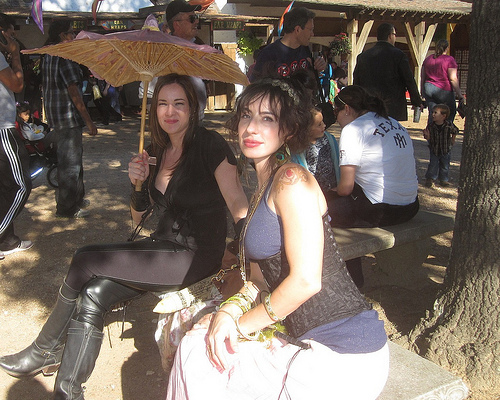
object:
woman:
[165, 80, 388, 400]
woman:
[1, 73, 248, 399]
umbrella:
[20, 13, 250, 192]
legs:
[1, 235, 192, 399]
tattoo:
[271, 164, 308, 195]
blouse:
[134, 124, 239, 254]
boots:
[0, 274, 145, 398]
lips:
[241, 140, 263, 150]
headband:
[238, 79, 302, 107]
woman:
[419, 38, 463, 129]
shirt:
[421, 53, 458, 92]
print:
[372, 114, 406, 139]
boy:
[421, 104, 459, 187]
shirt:
[427, 121, 460, 156]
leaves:
[236, 28, 263, 57]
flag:
[30, 0, 47, 36]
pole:
[23, 0, 33, 24]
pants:
[1, 127, 31, 249]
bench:
[373, 342, 470, 400]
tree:
[390, 1, 499, 399]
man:
[38, 16, 97, 219]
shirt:
[38, 47, 84, 131]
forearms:
[218, 278, 317, 334]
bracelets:
[214, 290, 285, 341]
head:
[152, 71, 205, 134]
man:
[353, 23, 422, 122]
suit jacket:
[351, 40, 421, 122]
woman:
[322, 84, 420, 226]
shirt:
[337, 109, 418, 205]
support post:
[346, 14, 373, 89]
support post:
[399, 16, 438, 97]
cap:
[165, 0, 203, 17]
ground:
[1, 111, 466, 399]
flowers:
[326, 29, 353, 60]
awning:
[262, 0, 472, 22]